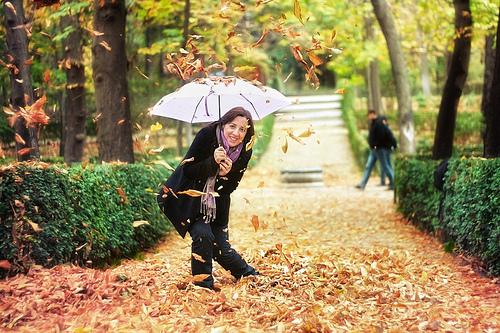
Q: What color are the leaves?
A: Orange.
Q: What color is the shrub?
A: Green.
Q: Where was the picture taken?
A: The park.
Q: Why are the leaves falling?
A: It is fall.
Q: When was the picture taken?
A: Daytime.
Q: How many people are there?
A: Three.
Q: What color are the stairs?
A: White.